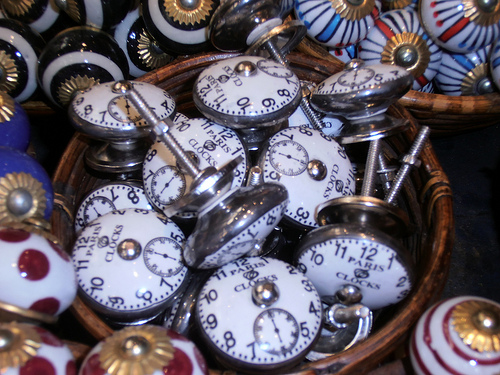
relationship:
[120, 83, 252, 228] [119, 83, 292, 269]
screw on knob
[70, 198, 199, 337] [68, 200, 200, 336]
clock on knob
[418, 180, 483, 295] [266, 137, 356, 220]
basket holds clock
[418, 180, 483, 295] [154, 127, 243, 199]
basket holds clock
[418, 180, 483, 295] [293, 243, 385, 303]
basket holds clock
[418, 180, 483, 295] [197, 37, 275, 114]
basket holds clock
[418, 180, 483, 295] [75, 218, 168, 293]
basket holds clock